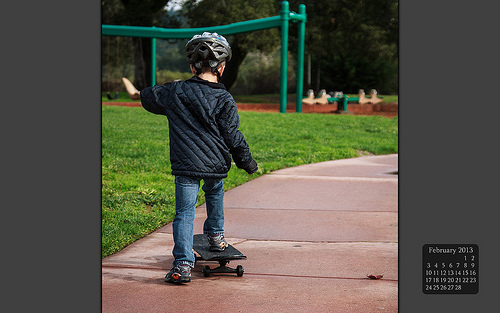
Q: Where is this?
A: This is at the park.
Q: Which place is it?
A: It is a park.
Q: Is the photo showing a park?
A: Yes, it is showing a park.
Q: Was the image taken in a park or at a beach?
A: It was taken at a park.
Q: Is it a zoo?
A: No, it is a park.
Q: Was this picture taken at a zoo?
A: No, the picture was taken in a park.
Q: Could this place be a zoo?
A: No, it is a park.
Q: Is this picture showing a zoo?
A: No, the picture is showing a park.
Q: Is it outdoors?
A: Yes, it is outdoors.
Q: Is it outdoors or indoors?
A: It is outdoors.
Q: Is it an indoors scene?
A: No, it is outdoors.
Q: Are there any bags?
A: No, there are no bags.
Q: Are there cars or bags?
A: No, there are no bags or cars.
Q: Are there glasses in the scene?
A: No, there are no glasses.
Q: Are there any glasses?
A: No, there are no glasses.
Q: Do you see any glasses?
A: No, there are no glasses.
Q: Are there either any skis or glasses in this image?
A: No, there are no glasses or skis.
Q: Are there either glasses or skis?
A: No, there are no glasses or skis.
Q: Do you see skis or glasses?
A: No, there are no glasses or skis.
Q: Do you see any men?
A: No, there are no men.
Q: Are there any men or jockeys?
A: No, there are no men or jockeys.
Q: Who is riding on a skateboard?
A: The boy is riding on a skateboard.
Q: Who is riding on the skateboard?
A: The boy is riding on a skateboard.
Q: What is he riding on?
A: The boy is riding on a skateboard.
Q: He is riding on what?
A: The boy is riding on a skateboard.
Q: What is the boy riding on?
A: The boy is riding on a skateboard.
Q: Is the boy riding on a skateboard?
A: Yes, the boy is riding on a skateboard.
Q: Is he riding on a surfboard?
A: No, the boy is riding on a skateboard.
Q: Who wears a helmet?
A: The boy wears a helmet.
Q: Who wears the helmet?
A: The boy wears a helmet.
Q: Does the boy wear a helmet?
A: Yes, the boy wears a helmet.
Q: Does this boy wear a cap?
A: No, the boy wears a helmet.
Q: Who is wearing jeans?
A: The boy is wearing jeans.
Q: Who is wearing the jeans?
A: The boy is wearing jeans.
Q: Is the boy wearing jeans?
A: Yes, the boy is wearing jeans.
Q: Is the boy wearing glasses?
A: No, the boy is wearing jeans.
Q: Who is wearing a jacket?
A: The boy is wearing a jacket.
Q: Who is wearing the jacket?
A: The boy is wearing a jacket.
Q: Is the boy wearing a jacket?
A: Yes, the boy is wearing a jacket.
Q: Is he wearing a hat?
A: No, the boy is wearing a jacket.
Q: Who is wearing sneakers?
A: The boy is wearing sneakers.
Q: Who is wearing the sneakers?
A: The boy is wearing sneakers.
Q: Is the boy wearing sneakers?
A: Yes, the boy is wearing sneakers.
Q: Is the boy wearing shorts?
A: No, the boy is wearing sneakers.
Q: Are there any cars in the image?
A: No, there are no cars.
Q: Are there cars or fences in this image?
A: No, there are no cars or fences.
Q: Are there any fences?
A: No, there are no fences.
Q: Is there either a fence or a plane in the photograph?
A: No, there are no fences or airplanes.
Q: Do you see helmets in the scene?
A: Yes, there is a helmet.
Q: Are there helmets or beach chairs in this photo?
A: Yes, there is a helmet.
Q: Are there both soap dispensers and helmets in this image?
A: No, there is a helmet but no soap dispensers.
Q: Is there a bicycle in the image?
A: No, there are no bicycles.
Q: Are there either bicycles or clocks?
A: No, there are no bicycles or clocks.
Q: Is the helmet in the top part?
A: Yes, the helmet is in the top of the image.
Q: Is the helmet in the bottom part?
A: No, the helmet is in the top of the image.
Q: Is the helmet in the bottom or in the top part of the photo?
A: The helmet is in the top of the image.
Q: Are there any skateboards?
A: Yes, there is a skateboard.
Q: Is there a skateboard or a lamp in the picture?
A: Yes, there is a skateboard.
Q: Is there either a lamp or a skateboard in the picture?
A: Yes, there is a skateboard.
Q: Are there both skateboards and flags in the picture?
A: No, there is a skateboard but no flags.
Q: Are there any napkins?
A: No, there are no napkins.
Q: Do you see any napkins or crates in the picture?
A: No, there are no napkins or crates.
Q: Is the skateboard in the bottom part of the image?
A: Yes, the skateboard is in the bottom of the image.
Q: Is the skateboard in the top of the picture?
A: No, the skateboard is in the bottom of the image.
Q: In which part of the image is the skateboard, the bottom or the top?
A: The skateboard is in the bottom of the image.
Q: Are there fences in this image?
A: No, there are no fences.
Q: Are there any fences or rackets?
A: No, there are no fences or rackets.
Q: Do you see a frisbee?
A: No, there are no frisbees.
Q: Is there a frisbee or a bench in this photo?
A: No, there are no frisbees or benches.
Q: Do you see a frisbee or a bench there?
A: No, there are no frisbees or benches.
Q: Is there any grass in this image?
A: Yes, there is grass.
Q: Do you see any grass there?
A: Yes, there is grass.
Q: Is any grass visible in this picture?
A: Yes, there is grass.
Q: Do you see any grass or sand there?
A: Yes, there is grass.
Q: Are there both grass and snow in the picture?
A: No, there is grass but no snow.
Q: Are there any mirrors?
A: No, there are no mirrors.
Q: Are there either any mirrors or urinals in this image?
A: No, there are no mirrors or urinals.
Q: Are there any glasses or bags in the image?
A: No, there are no glasses or bags.